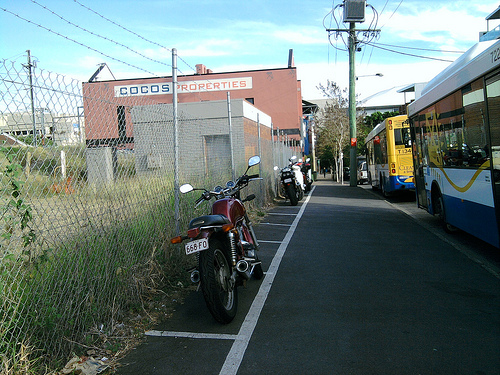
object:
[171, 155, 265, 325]
motorcycle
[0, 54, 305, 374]
fence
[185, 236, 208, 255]
license plate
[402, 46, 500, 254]
bus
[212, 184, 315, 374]
white line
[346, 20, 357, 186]
pole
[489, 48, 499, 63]
722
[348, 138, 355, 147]
sign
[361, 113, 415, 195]
bus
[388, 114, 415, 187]
back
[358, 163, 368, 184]
minivan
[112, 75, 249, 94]
sign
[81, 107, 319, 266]
building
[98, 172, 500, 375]
sidewalk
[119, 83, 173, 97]
letters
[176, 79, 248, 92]
letters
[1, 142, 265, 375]
grass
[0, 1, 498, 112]
sky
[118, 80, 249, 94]
cocos properties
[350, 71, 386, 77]
streetlight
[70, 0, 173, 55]
barbed wire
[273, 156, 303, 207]
motorcycles